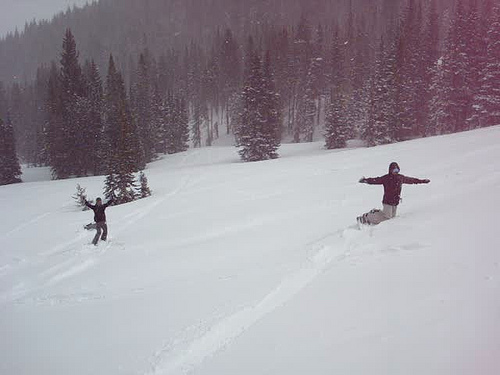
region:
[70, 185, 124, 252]
Person standing in the snow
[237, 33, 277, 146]
Snow on a green tree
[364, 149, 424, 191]
Person standing with their hands out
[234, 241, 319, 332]
Trail in the snow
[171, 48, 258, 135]
Pine trees in the background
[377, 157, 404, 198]
Person in a hooded coat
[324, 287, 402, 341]
Flat snow on a hill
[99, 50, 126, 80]
Top of a pine tree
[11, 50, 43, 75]
Dark sky over trees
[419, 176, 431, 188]
Black glove on a person's hand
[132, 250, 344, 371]
a ground covered in snow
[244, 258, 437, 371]
a ground covered in white snow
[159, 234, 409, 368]
snow covering the ground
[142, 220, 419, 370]
white snow covering the ground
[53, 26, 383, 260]
trees in the snow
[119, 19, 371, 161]
snow on the trees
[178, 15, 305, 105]
white snow on the trees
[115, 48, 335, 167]
trees with snow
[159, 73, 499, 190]
trees with white snow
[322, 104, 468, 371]
a person in the snow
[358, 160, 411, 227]
person bent on knees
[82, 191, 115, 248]
person in distance going uphill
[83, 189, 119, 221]
person raising hands up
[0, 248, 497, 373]
most the ground cover in snow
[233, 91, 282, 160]
large pine tree in back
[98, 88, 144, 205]
large tree near person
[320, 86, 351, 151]
pine tree in distance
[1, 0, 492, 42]
trees cover hill in distance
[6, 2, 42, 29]
sky is blueish grey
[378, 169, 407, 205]
person is wearing jacket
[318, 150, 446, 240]
this person is snowboarding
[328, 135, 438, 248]
they are kneeling in the snow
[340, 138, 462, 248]
this person is holding their arms out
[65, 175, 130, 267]
this person is holding their arms in the air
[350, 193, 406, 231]
the pants are a light tan color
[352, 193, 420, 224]
khaki colored ski pants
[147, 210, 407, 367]
the person made deep tracks in the snow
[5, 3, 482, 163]
the forest is hazy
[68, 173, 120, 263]
this person has a black jacket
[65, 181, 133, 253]
they are wearing a black jacket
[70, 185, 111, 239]
skier